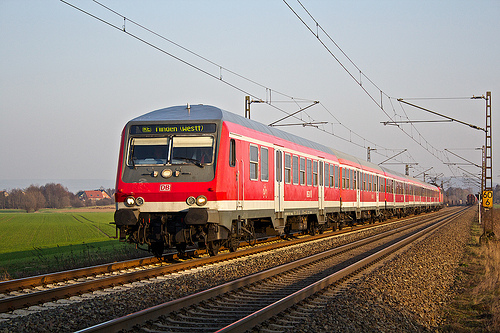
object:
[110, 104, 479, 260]
train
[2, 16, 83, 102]
sky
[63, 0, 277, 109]
wires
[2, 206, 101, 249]
field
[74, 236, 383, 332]
track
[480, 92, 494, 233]
pole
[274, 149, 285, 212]
doors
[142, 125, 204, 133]
information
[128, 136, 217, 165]
windshield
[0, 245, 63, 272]
weeds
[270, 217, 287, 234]
step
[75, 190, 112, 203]
house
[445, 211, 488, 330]
grass